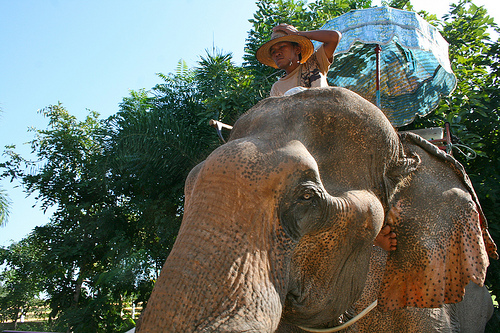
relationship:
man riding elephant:
[258, 12, 344, 94] [136, 89, 499, 331]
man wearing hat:
[253, 23, 343, 97] [255, 24, 318, 61]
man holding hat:
[253, 23, 343, 97] [250, 21, 318, 72]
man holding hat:
[253, 23, 343, 97] [242, 17, 319, 68]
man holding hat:
[253, 23, 343, 97] [249, 21, 315, 68]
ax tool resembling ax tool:
[205, 119, 235, 144] [202, 116, 234, 144]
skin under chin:
[293, 255, 368, 329] [294, 237, 333, 320]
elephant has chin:
[108, 83, 467, 331] [294, 237, 333, 320]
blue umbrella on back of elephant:
[311, 7, 458, 129] [136, 89, 499, 331]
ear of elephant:
[377, 130, 497, 313] [136, 89, 499, 331]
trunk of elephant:
[156, 211, 292, 331] [231, 90, 474, 330]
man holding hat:
[253, 23, 343, 97] [246, 23, 342, 85]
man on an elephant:
[253, 23, 343, 97] [28, 59, 481, 324]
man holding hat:
[253, 23, 343, 97] [239, 16, 327, 72]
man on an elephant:
[253, 23, 343, 97] [72, 24, 496, 329]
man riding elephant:
[253, 23, 343, 97] [162, 90, 478, 322]